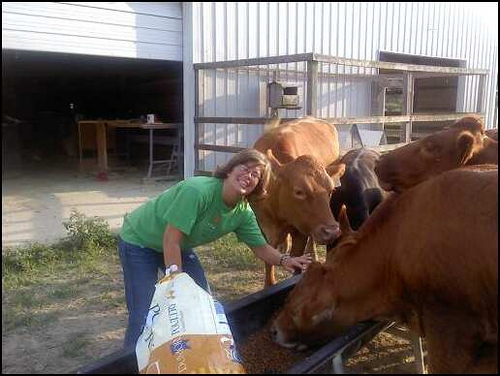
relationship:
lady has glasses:
[118, 150, 311, 347] [231, 162, 260, 178]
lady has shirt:
[118, 150, 311, 347] [118, 175, 266, 252]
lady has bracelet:
[118, 150, 311, 347] [277, 255, 291, 267]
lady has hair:
[118, 150, 311, 347] [214, 150, 271, 204]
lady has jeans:
[118, 150, 311, 347] [119, 235, 213, 351]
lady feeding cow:
[118, 150, 311, 347] [326, 145, 390, 244]